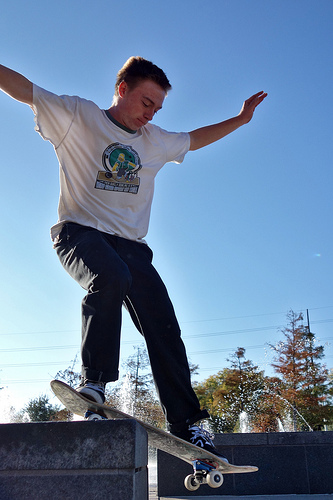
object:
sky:
[0, 0, 332, 329]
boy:
[0, 56, 268, 464]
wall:
[0, 421, 149, 500]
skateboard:
[49, 378, 258, 491]